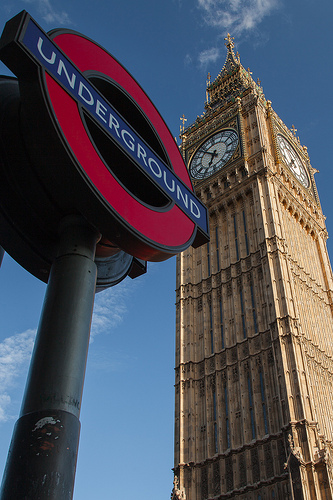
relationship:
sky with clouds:
[3, 1, 327, 499] [0, 3, 328, 497]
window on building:
[260, 401, 267, 411] [170, 31, 331, 499]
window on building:
[229, 205, 255, 245] [170, 31, 331, 499]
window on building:
[238, 285, 248, 339] [170, 31, 331, 499]